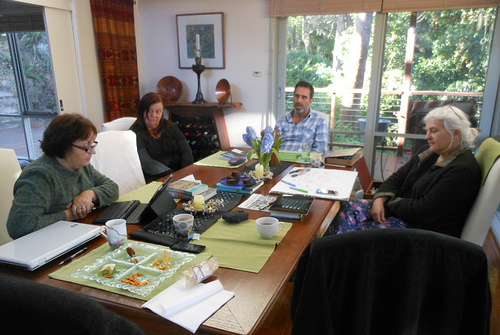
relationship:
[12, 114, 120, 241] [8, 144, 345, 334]
person sitting around table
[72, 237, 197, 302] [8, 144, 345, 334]
bowl on table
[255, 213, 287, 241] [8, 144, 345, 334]
cup on table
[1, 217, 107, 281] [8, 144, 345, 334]
laptop on table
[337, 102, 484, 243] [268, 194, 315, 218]
lady looking at tablet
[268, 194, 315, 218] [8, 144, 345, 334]
tablet on table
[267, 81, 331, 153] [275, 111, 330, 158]
man wearing shirt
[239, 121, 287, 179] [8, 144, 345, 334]
plant on table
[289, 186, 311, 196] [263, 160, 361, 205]
pen on paper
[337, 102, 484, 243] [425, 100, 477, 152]
lady has hair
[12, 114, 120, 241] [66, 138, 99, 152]
person wearing glasses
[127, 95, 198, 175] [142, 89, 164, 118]
woman has hair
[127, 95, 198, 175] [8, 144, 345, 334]
woman sitting around table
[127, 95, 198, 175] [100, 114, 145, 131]
woman sitting in chair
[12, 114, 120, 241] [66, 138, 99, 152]
person with glasses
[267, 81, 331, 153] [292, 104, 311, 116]
man has beard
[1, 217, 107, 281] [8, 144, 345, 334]
laptop placed on table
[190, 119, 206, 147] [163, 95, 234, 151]
book sitting on shelf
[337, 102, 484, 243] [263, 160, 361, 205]
woman looking at notebook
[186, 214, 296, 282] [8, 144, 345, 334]
mat on table